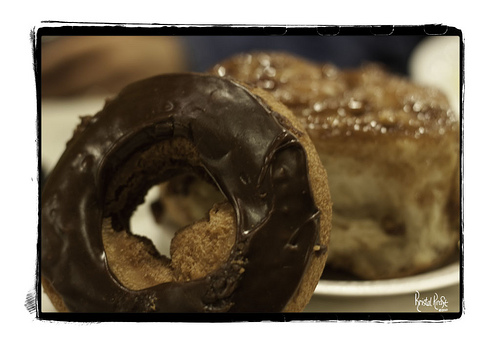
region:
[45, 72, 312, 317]
chcolate frosting on a donut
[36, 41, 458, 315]
two types of pastries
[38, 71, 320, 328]
donut with frosting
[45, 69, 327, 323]
donut with chocolate frosting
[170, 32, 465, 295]
cinnamon roll on a white plate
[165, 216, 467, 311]
white plate with a pastry on top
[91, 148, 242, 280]
hole at the center of the donut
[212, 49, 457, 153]
top of the roll is shiny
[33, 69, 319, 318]
frosting on the donut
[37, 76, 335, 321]
round pastry with frosting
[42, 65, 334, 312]
chocolate frosted round donut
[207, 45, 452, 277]
cinnamon roll on a plate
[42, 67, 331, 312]
chocolate donut leaning on cinnamon roll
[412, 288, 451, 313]
name of photography company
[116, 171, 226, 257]
hole in the middle of the donut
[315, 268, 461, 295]
edge of white plate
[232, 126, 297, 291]
chocolate frosting on donut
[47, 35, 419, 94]
blurry image of somones arm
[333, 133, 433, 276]
cut edge of cinnamon roll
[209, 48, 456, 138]
glaze on top of cinnamon roll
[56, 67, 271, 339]
The donut is round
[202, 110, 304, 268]
Chocolate frosting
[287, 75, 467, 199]
Shiny donut in the back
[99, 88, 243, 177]
Brown frosting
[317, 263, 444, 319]
Plate is white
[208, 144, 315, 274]
The frosting has bumps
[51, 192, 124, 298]
The frosting is shiny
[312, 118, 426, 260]
The donut in the back is shiny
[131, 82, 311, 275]
The frosting is made of sugar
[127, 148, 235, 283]
large hole in a donut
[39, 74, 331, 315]
chocolate covered donut standing upright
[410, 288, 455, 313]
credit of the photographer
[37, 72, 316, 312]
chocolate icing on a donut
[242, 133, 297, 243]
a swirl on top of the donut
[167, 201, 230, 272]
a bulge in the dough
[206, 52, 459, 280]
a pastry behind the donut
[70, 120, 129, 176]
a light reflecting on the donut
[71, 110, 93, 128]
a point of the icing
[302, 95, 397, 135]
light glistening off of the pastry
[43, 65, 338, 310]
Chocolate glazed cake donut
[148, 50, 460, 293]
Cinnamon bun sitting on plate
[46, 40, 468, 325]
Two donuts sitting on table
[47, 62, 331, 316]
Donut with bumpy chocolate frosting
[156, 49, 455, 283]
Circular pastry with glaze on top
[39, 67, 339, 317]
Round donut sitting up on end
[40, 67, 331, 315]
Donut with frosting only on top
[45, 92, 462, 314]
White plate sitting on off white table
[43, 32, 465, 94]
Blurry hand and arm of person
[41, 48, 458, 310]
A table with two donuts